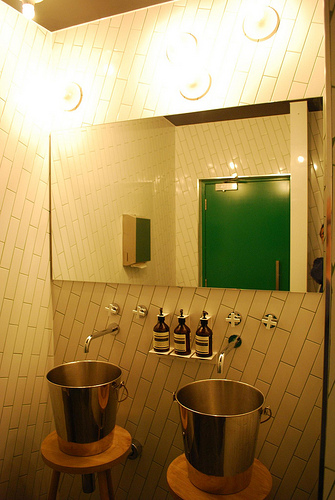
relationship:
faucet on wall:
[217, 335, 242, 375] [208, 477, 244, 490]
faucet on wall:
[72, 321, 121, 354] [208, 477, 244, 490]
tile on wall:
[195, 129, 270, 164] [1, 1, 323, 497]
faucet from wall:
[217, 333, 241, 370] [51, 0, 333, 499]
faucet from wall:
[84, 322, 120, 353] [51, 0, 333, 499]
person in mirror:
[310, 222, 324, 291] [37, 97, 322, 295]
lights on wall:
[42, 56, 268, 153] [106, 126, 195, 177]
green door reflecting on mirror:
[213, 185, 286, 281] [44, 102, 331, 313]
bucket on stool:
[173, 378, 272, 495] [40, 424, 131, 499]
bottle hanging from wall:
[195, 310, 214, 356] [51, 0, 333, 499]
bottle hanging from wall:
[173, 308, 190, 353] [51, 0, 333, 499]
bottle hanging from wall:
[153, 307, 169, 350] [51, 0, 333, 499]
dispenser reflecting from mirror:
[119, 213, 150, 265] [37, 97, 322, 295]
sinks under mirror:
[172, 376, 270, 488] [37, 97, 322, 295]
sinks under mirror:
[43, 360, 120, 458] [37, 97, 322, 295]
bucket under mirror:
[41, 357, 128, 452] [37, 97, 322, 295]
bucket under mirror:
[171, 374, 277, 492] [37, 97, 322, 295]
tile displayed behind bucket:
[50, 284, 314, 498] [171, 374, 277, 492]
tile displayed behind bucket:
[50, 284, 314, 498] [45, 359, 129, 456]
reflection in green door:
[304, 225, 330, 281] [200, 179, 290, 292]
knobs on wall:
[103, 299, 280, 338] [40, 38, 311, 452]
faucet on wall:
[84, 322, 120, 353] [54, 278, 317, 485]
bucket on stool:
[45, 359, 129, 456] [40, 424, 131, 498]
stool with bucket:
[40, 424, 131, 498] [45, 359, 129, 456]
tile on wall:
[50, 284, 314, 498] [19, 203, 322, 498]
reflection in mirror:
[302, 219, 320, 284] [44, 102, 331, 313]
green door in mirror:
[200, 179, 290, 292] [37, 97, 322, 295]